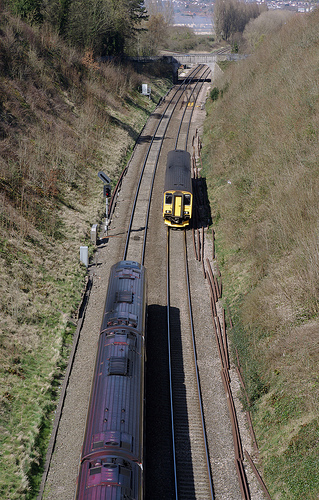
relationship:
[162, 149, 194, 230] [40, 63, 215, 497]
car on rail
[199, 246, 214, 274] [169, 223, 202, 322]
gravel around tracks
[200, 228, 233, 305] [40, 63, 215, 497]
board next to rail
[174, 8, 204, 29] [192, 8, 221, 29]
body of water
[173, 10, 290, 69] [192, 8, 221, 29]
building across water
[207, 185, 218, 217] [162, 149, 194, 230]
shadow from car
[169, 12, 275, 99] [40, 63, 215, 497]
bridge over rail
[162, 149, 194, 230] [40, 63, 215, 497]
car has rail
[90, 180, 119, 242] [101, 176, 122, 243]
pole for signal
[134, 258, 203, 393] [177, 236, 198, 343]
rail on ground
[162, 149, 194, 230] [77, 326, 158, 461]
car with car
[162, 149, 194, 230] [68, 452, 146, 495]
car with car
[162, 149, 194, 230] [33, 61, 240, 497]
car on tracks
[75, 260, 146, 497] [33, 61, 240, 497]
car on tracks